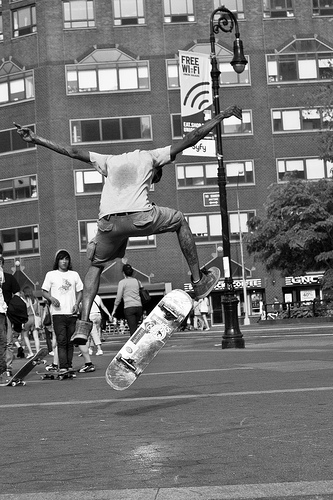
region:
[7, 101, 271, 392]
skateboarder elevated over board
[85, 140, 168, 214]
round patch of sweat on back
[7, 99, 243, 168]
arms curved upwards overhead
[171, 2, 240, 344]
banner hanging on tall lamppost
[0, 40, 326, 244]
brick building with horizontal windows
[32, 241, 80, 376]
skateboarder looking forward with hood over head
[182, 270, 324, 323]
railing and people in front of stores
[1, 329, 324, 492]
paving with stripes, marks and scratches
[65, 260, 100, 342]
thick ankle shoe on narrow leg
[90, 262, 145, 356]
two people holding hands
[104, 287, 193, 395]
a skateboard in the air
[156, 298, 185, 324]
wheels of the skateboard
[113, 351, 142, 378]
wheels on the skateboard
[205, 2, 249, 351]
a light post on sidewalk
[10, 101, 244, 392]
a guy doing a skateboarding trick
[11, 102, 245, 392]
a guy skateboarding in air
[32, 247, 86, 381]
a guy on skateboard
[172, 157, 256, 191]
windows on the building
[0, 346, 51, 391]
a skateboard on ground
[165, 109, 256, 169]
hand of the boy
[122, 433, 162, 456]
white mark in road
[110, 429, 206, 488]
a small mark in road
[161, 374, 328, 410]
white line on the road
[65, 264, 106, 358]
legs of the man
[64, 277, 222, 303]
a man in air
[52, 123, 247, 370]
a man jumping in to air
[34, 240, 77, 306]
a boy looking the man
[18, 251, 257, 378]
a group of people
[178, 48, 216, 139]
white sign on post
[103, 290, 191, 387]
white painted skate board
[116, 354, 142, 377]
black tires on skate board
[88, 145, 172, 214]
white cotton tee shirt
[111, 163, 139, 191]
sweat on mans back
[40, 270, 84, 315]
white cotton tee shirt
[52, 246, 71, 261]
cap on mans head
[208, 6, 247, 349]
black iron lamp post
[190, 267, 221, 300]
high top skate shoes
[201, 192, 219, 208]
sign on brick building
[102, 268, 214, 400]
skate board in the air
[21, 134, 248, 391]
man doing a trick on a skateboard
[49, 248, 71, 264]
man wearing a hat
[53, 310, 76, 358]
boy wearing black pants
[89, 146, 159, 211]
boy wearing a gray shirt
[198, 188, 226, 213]
shirt sign on a pole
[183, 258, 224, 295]
boy wearing nike sneakers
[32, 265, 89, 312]
man wearing a white tee shirt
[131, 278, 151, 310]
woman holding a black purse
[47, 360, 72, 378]
guy foot on a skateboard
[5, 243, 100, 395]
a group of people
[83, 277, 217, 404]
skateboard in the air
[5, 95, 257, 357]
man in the air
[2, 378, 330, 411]
line on the ground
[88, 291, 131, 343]
people are holding hands